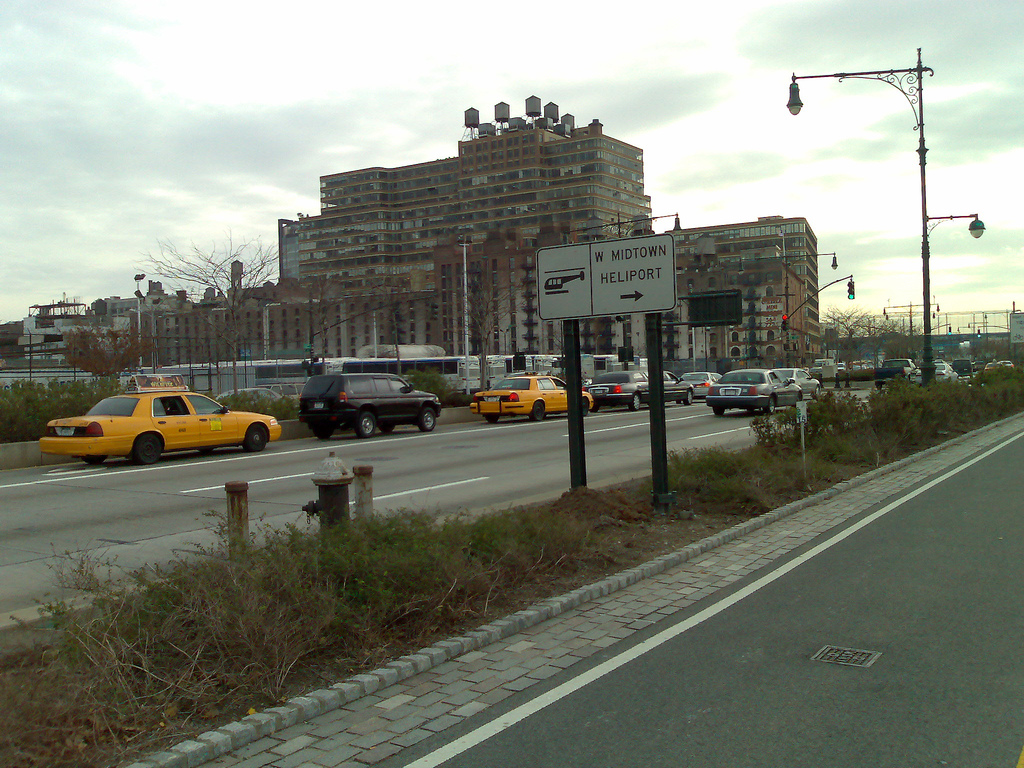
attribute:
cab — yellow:
[35, 370, 288, 470]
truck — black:
[299, 368, 444, 436]